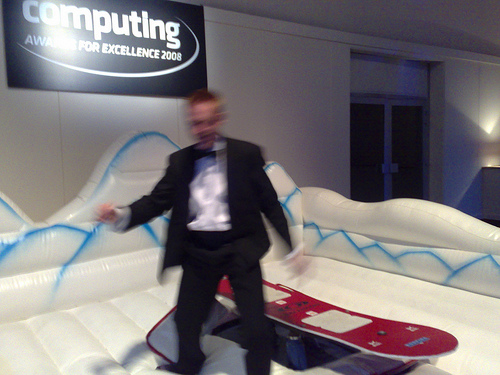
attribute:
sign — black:
[2, 0, 209, 104]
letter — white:
[92, 10, 112, 42]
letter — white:
[165, 21, 180, 50]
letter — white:
[130, 12, 143, 40]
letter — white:
[61, 4, 92, 33]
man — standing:
[96, 86, 306, 374]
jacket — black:
[115, 139, 297, 283]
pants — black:
[163, 233, 273, 374]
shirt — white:
[183, 140, 231, 233]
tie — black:
[192, 146, 219, 161]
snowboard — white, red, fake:
[218, 274, 459, 361]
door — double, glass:
[352, 98, 431, 205]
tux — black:
[116, 143, 296, 374]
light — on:
[483, 164, 499, 181]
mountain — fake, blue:
[3, 130, 302, 275]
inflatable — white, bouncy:
[2, 132, 499, 373]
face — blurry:
[189, 91, 227, 149]